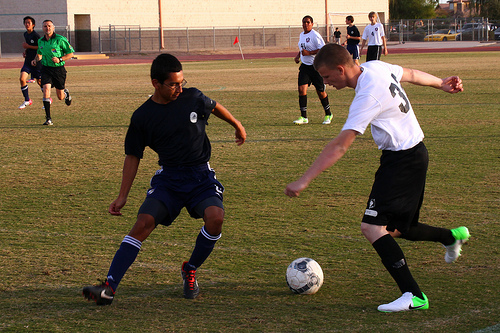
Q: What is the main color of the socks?
A: Black.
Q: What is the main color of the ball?
A: White.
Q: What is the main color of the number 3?
A: Black.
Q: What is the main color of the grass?
A: Green.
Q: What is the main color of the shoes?
A: White.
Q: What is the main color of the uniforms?
A: Black.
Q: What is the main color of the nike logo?
A: Black.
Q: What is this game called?
A: Soccer.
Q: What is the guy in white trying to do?
A: Kick the ball before other guy.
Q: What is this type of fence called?
A: Chain link fence.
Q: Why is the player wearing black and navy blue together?
A: That is his team colors.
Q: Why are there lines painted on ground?
A: To show players where the out of bounds and distances are.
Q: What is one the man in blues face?
A: Eye glasses.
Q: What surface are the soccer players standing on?
A: Grass.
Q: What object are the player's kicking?
A: A soccer ball.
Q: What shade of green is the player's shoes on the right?
A: Neon green.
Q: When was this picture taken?
A: Late afternoon.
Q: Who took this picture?
A: A spectator.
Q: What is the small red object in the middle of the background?
A: A flag.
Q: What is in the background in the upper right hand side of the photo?
A: Cars.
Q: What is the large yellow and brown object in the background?
A: A building.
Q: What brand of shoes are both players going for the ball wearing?
A: Nike.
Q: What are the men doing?
A: Playing soccer.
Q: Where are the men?
A: The field.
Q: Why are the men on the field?
A: Playing a game.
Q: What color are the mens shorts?
A: Black.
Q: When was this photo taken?
A: Evening time.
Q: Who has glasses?
A: A man.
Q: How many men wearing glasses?
A: One.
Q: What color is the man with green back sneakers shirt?
A: White.